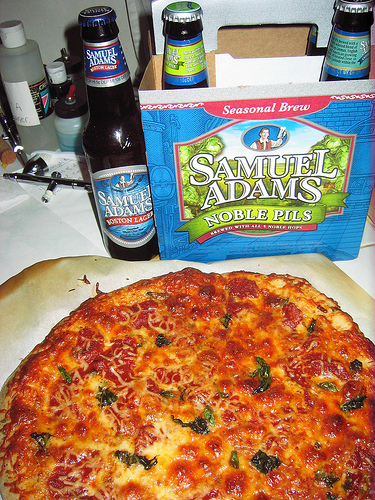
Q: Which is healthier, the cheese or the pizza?
A: The cheese is healthier than the pizza.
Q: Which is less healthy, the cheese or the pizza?
A: The pizza is less healthy than the cheese.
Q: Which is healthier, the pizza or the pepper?
A: The pepper is healthier than the pizza.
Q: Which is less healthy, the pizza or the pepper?
A: The pizza is less healthy than the pepper.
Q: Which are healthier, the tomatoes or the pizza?
A: The tomatoes are healthier than the pizza.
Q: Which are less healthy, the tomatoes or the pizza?
A: The pizza are less healthy than the tomatoes.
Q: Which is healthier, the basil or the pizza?
A: The basil is healthier than the pizza.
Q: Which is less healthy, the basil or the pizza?
A: The pizza is less healthy than the basil.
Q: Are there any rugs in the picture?
A: No, there are no rugs.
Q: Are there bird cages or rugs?
A: No, there are no rugs or bird cages.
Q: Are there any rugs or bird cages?
A: No, there are no rugs or bird cages.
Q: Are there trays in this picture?
A: No, there are no trays.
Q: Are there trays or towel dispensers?
A: No, there are no trays or towel dispensers.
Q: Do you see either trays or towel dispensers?
A: No, there are no trays or towel dispensers.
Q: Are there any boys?
A: No, there are no boys.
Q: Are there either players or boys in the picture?
A: No, there are no boys or players.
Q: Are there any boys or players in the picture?
A: No, there are no boys or players.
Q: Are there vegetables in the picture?
A: Yes, there are vegetables.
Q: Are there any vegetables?
A: Yes, there are vegetables.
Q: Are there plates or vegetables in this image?
A: Yes, there are vegetables.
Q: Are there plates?
A: No, there are no plates.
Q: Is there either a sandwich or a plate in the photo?
A: No, there are no plates or sandwiches.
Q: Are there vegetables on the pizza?
A: Yes, there are vegetables on the pizza.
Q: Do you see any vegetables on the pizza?
A: Yes, there are vegetables on the pizza.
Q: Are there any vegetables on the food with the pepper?
A: Yes, there are vegetables on the pizza.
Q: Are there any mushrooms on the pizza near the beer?
A: No, there are vegetables on the pizza.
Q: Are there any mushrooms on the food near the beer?
A: No, there are vegetables on the pizza.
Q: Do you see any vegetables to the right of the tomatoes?
A: Yes, there are vegetables to the right of the tomatoes.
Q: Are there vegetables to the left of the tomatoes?
A: No, the vegetables are to the right of the tomatoes.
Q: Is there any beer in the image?
A: Yes, there is beer.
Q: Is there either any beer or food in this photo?
A: Yes, there is beer.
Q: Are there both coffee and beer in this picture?
A: No, there is beer but no coffee.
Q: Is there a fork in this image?
A: No, there are no forks.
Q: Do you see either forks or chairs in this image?
A: No, there are no forks or chairs.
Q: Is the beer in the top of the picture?
A: Yes, the beer is in the top of the image.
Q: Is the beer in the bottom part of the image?
A: No, the beer is in the top of the image.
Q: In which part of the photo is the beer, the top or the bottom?
A: The beer is in the top of the image.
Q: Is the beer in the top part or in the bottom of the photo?
A: The beer is in the top of the image.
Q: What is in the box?
A: The beer is in the box.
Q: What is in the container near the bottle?
A: The beer is in the box.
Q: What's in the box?
A: The beer is in the box.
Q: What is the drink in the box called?
A: The drink is beer.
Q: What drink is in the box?
A: The drink is beer.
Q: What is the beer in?
A: The beer is in the box.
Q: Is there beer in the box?
A: Yes, there is beer in the box.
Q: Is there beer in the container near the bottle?
A: Yes, there is beer in the box.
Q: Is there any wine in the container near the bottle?
A: No, there is beer in the box.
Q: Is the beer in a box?
A: Yes, the beer is in a box.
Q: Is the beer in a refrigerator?
A: No, the beer is in a box.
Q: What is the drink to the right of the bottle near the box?
A: The drink is beer.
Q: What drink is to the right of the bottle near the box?
A: The drink is beer.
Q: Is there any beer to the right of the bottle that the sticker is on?
A: Yes, there is beer to the right of the bottle.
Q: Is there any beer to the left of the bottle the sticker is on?
A: No, the beer is to the right of the bottle.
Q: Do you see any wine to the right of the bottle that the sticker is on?
A: No, there is beer to the right of the bottle.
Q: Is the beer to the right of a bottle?
A: Yes, the beer is to the right of a bottle.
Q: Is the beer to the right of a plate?
A: No, the beer is to the right of a bottle.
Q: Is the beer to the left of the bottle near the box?
A: No, the beer is to the right of the bottle.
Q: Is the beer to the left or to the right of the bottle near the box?
A: The beer is to the right of the bottle.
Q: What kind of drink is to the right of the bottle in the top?
A: The drink is beer.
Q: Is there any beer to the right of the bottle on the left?
A: Yes, there is beer to the right of the bottle.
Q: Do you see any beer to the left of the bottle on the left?
A: No, the beer is to the right of the bottle.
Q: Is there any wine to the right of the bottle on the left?
A: No, there is beer to the right of the bottle.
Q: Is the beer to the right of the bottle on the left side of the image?
A: Yes, the beer is to the right of the bottle.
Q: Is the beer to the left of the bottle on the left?
A: No, the beer is to the right of the bottle.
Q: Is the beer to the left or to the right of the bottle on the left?
A: The beer is to the right of the bottle.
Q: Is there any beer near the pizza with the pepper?
A: Yes, there is beer near the pizza.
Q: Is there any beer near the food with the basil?
A: Yes, there is beer near the pizza.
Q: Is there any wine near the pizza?
A: No, there is beer near the pizza.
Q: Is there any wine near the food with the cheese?
A: No, there is beer near the pizza.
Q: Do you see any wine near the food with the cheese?
A: No, there is beer near the pizza.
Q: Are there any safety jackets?
A: No, there are no safety jackets.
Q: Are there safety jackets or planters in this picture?
A: No, there are no safety jackets or planters.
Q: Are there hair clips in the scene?
A: No, there are no hair clips.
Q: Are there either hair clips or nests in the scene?
A: No, there are no hair clips or nests.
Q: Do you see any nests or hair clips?
A: No, there are no hair clips or nests.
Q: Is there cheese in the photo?
A: Yes, there is cheese.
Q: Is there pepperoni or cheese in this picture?
A: Yes, there is cheese.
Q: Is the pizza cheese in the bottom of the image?
A: Yes, the cheese is in the bottom of the image.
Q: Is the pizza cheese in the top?
A: No, the cheese is in the bottom of the image.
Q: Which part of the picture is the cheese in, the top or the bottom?
A: The cheese is in the bottom of the image.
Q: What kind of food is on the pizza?
A: The food is cheese.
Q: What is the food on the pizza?
A: The food is cheese.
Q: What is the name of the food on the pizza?
A: The food is cheese.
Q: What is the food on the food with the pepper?
A: The food is cheese.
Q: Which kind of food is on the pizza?
A: The food is cheese.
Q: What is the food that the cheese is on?
A: The food is a pizza.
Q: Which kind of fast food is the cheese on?
A: The cheese is on the pizza.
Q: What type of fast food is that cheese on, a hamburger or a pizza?
A: The cheese is on a pizza.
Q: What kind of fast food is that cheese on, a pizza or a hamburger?
A: The cheese is on a pizza.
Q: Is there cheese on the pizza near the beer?
A: Yes, there is cheese on the pizza.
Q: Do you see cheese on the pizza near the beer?
A: Yes, there is cheese on the pizza.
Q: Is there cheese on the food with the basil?
A: Yes, there is cheese on the pizza.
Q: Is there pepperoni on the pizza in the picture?
A: No, there is cheese on the pizza.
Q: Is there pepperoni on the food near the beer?
A: No, there is cheese on the pizza.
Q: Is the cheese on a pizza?
A: Yes, the cheese is on a pizza.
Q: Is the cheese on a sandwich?
A: No, the cheese is on a pizza.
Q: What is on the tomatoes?
A: The cheese is on the tomatoes.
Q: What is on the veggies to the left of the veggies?
A: The cheese is on the tomatoes.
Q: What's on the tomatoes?
A: The cheese is on the tomatoes.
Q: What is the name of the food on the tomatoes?
A: The food is cheese.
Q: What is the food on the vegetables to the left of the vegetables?
A: The food is cheese.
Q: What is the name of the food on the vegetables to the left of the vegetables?
A: The food is cheese.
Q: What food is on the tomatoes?
A: The food is cheese.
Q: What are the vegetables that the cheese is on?
A: The vegetables are tomatoes.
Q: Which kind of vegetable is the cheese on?
A: The cheese is on the tomatoes.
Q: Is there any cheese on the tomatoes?
A: Yes, there is cheese on the tomatoes.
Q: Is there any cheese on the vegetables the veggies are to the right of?
A: Yes, there is cheese on the tomatoes.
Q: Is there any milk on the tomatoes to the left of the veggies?
A: No, there is cheese on the tomatoes.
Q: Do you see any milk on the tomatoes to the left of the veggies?
A: No, there is cheese on the tomatoes.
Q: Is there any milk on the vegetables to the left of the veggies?
A: No, there is cheese on the tomatoes.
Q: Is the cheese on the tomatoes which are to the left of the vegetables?
A: Yes, the cheese is on the tomatoes.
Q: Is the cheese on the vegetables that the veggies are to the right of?
A: Yes, the cheese is on the tomatoes.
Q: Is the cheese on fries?
A: No, the cheese is on the tomatoes.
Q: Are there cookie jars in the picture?
A: No, there are no cookie jars.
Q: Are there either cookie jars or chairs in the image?
A: No, there are no cookie jars or chairs.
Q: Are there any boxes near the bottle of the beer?
A: Yes, there is a box near the bottle.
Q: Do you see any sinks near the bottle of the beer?
A: No, there is a box near the bottle.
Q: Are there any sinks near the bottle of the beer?
A: No, there is a box near the bottle.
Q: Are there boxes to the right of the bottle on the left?
A: Yes, there is a box to the right of the bottle.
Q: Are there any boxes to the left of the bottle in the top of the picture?
A: No, the box is to the right of the bottle.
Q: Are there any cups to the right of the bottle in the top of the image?
A: No, there is a box to the right of the bottle.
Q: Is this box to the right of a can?
A: No, the box is to the right of the bottle.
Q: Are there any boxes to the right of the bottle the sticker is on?
A: Yes, there is a box to the right of the bottle.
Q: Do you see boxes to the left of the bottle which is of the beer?
A: No, the box is to the right of the bottle.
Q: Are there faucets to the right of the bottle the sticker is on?
A: No, there is a box to the right of the bottle.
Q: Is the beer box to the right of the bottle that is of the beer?
A: Yes, the box is to the right of the bottle.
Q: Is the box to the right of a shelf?
A: No, the box is to the right of the bottle.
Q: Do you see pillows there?
A: No, there are no pillows.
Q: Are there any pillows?
A: No, there are no pillows.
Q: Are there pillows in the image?
A: No, there are no pillows.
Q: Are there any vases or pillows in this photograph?
A: No, there are no pillows or vases.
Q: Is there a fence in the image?
A: No, there are no fences.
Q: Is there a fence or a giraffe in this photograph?
A: No, there are no fences or giraffes.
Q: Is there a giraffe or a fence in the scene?
A: No, there are no fences or giraffes.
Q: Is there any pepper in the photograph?
A: Yes, there is a pepper.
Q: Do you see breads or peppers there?
A: Yes, there is a pepper.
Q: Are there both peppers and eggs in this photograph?
A: No, there is a pepper but no eggs.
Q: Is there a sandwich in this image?
A: No, there are no sandwiches.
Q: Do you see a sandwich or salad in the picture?
A: No, there are no sandwiches or salad.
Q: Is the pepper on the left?
A: Yes, the pepper is on the left of the image.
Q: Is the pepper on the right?
A: No, the pepper is on the left of the image.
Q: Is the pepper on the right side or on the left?
A: The pepper is on the left of the image.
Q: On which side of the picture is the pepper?
A: The pepper is on the left of the image.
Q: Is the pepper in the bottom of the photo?
A: Yes, the pepper is in the bottom of the image.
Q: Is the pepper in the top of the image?
A: No, the pepper is in the bottom of the image.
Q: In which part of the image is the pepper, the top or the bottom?
A: The pepper is in the bottom of the image.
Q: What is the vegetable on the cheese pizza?
A: The vegetable is a pepper.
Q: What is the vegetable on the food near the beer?
A: The vegetable is a pepper.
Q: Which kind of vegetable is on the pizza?
A: The vegetable is a pepper.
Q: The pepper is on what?
A: The pepper is on the pizza.